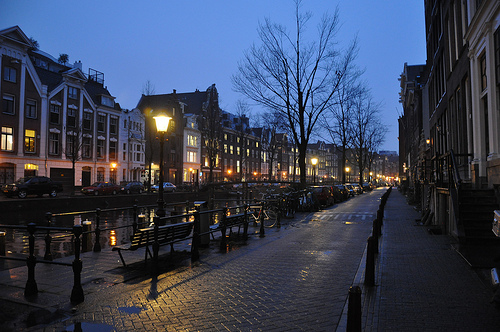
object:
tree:
[228, 0, 365, 192]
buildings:
[139, 82, 267, 186]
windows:
[189, 147, 194, 164]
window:
[474, 45, 492, 93]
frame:
[472, 86, 491, 164]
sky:
[0, 1, 427, 154]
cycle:
[253, 196, 283, 228]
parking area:
[241, 176, 373, 226]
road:
[0, 186, 500, 332]